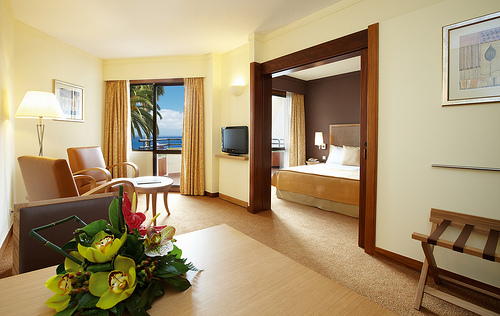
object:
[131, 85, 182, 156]
window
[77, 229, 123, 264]
flower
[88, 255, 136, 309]
flower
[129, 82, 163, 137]
palm tree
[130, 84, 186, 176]
door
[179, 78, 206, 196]
curtains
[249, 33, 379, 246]
entranceway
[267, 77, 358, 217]
bedroom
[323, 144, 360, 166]
pillows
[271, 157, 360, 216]
bed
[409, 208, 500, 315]
stand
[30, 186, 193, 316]
plants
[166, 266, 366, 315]
table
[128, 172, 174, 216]
table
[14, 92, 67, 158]
lamp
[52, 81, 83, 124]
painting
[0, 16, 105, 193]
wall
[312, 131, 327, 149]
lamp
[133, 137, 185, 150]
ocean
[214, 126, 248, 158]
tv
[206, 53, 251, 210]
wall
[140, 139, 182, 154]
balcony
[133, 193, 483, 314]
carpet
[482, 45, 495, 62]
leaf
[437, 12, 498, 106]
picture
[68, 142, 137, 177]
chairs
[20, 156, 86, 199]
chair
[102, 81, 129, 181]
cutain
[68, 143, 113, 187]
cushions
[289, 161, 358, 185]
cover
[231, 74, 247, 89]
lamp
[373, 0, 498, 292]
wall